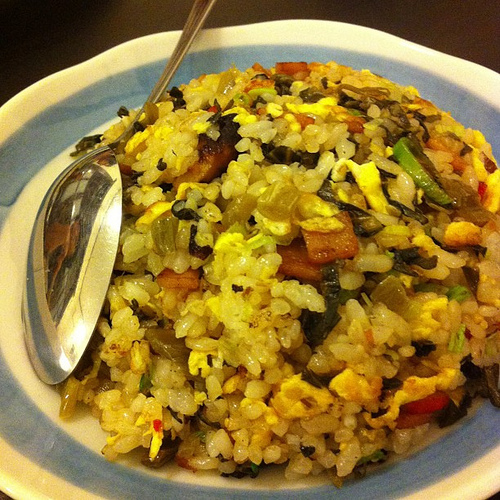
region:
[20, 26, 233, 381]
the spoon is silver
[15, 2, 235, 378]
the spoon is resting in the bowl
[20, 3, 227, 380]
the spoon is shiny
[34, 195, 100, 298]
a reflection in the spoon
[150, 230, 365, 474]
rice in the bowl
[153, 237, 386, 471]
the rice is white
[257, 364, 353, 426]
cheese in the rice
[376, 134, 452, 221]
green peppers in the rice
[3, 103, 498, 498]
blue stripe on the bowl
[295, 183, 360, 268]
brown pieces of food in the rice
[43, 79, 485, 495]
This is a bowl of food.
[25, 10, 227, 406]
The spoon appears large.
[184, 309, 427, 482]
Rice is the main ingredient.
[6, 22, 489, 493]
The bowl is blue and white.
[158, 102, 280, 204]
This dish may contain meat.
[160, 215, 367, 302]
These may be onions.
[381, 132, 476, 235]
Some green is showing.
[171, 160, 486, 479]
This may contain other grains like barley.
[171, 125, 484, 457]
This is a healthy meal.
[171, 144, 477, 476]
There are many ingredients.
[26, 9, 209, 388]
a silver spoon laying in a dish of food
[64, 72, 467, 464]
a rice dish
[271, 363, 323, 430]
tiny yellow bits of egg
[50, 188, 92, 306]
reflections in the spoon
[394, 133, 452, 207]
a bit of green food mixed in with the rice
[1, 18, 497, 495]
a circular white plate with a blue rim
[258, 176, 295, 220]
a tiny bit of pepper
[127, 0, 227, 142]
the silver handle of a spoon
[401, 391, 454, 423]
a tiny bit of red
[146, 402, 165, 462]
a bit of egg with a spot of red on it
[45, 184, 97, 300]
a persons reflection in the spoon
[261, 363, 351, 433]
a piece of scrambled egg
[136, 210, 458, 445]
an egg and vegetable rice dish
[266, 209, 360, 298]
a few pieces of pepper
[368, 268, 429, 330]
a sauteed piece of onion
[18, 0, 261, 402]
a shiny silver spoon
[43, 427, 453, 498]
a faded blue stripe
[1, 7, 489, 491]
a white and blue plate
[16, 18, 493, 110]
a wavy plate rim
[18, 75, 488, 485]
a meal on a china plate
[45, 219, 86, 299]
reflection of a person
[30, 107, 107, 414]
A spoon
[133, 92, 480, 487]
A plate of fried rice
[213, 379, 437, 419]
Cooked eggs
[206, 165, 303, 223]
chopped up onions for the rice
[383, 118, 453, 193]
A chopped up green pepper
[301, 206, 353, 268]
A chopped up red pepper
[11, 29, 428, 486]
A white and blue plate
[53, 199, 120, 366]
reflections of light in the spoon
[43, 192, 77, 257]
reflection of the phone taking the picture.